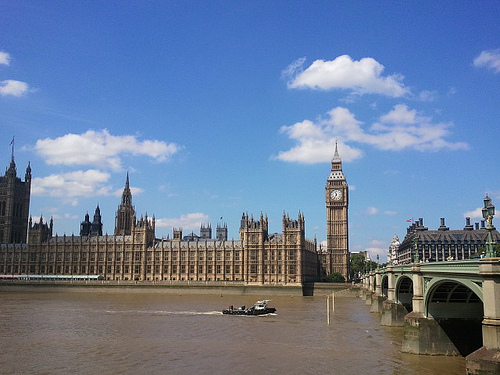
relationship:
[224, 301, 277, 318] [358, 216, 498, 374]
boat by bridge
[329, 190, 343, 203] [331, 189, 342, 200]
clock tells time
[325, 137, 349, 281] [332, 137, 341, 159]
building with point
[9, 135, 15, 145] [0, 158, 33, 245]
flag on building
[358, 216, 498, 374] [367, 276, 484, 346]
bridge has arches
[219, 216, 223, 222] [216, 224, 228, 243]
flag on top of building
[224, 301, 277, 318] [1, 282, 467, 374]
boat on river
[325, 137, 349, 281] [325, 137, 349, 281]
clocktower of clocktower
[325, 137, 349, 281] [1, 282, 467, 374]
big ben next to river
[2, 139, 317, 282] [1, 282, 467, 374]
house of parliament next to river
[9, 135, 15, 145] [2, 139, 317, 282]
flag on house of parliament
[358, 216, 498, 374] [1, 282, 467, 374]
bridge over water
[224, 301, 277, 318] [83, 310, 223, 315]
boat leaves trail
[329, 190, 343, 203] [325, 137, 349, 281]
clock of big ben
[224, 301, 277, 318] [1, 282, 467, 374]
vessel on water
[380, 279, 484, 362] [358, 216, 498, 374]
passeges under bridge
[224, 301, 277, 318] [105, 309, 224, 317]
boat leaves a wake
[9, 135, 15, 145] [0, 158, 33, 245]
flag on top of tower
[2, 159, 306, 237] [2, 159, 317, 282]
towers on house of parliament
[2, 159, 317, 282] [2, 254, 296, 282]
house of parliament has windows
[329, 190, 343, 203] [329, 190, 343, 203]
white face of clock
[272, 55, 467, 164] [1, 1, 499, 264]
clouds in sky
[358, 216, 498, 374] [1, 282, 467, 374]
bridge crossing river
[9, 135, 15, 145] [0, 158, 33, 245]
flag on top of building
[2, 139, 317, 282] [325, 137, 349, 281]
parliament building in clocktower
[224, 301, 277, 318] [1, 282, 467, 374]
boat on water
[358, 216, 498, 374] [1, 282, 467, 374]
bridge stretching across river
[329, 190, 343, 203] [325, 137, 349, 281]
white face on clocktower